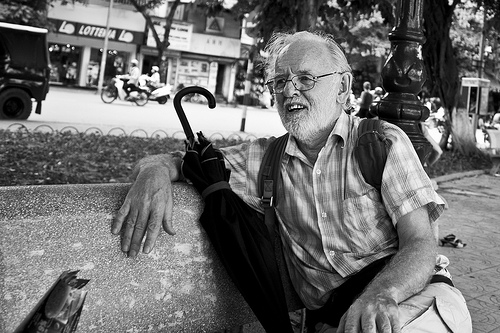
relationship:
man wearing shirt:
[112, 28, 472, 330] [203, 117, 451, 289]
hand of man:
[100, 130, 195, 265] [112, 28, 472, 330]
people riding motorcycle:
[145, 66, 160, 92] [138, 76, 173, 106]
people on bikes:
[120, 52, 162, 103] [97, 64, 169, 105]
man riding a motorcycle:
[110, 30, 473, 333] [85, 59, 156, 111]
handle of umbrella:
[171, 84, 217, 139] [172, 85, 292, 331]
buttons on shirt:
[307, 162, 343, 284] [208, 113, 449, 305]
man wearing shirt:
[112, 28, 472, 330] [216, 107, 442, 316]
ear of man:
[331, 70, 353, 105] [112, 28, 472, 330]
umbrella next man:
[172, 85, 292, 331] [112, 28, 472, 330]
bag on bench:
[16, 262, 89, 330] [3, 171, 428, 320]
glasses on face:
[268, 72, 315, 91] [272, 56, 326, 138]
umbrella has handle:
[160, 77, 301, 332] [167, 80, 216, 149]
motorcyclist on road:
[99, 74, 217, 122] [43, 94, 203, 132]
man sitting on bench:
[112, 28, 472, 330] [0, 176, 307, 330]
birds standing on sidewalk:
[441, 228, 473, 250] [432, 166, 499, 329]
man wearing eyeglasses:
[112, 28, 472, 330] [261, 67, 344, 104]